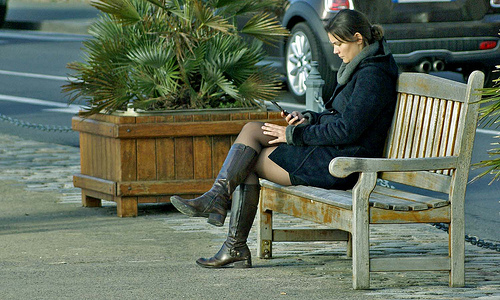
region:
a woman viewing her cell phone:
[170, 8, 399, 271]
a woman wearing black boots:
[168, 141, 262, 268]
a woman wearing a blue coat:
[268, 43, 400, 193]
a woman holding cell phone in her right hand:
[266, 98, 295, 120]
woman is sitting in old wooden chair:
[256, 69, 488, 291]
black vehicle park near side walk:
[136, 0, 498, 106]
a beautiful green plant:
[59, 1, 293, 109]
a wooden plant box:
[69, 103, 298, 218]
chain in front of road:
[0, 110, 498, 251]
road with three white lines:
[0, 31, 498, 242]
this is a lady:
[263, 26, 392, 153]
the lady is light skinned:
[257, 124, 274, 145]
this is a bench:
[354, 152, 475, 279]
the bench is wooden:
[348, 148, 396, 265]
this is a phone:
[271, 97, 301, 118]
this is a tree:
[145, 32, 218, 94]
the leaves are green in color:
[195, 49, 242, 85]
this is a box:
[91, 117, 174, 179]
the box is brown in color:
[116, 122, 177, 177]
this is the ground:
[44, 214, 134, 296]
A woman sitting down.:
[167, 6, 397, 270]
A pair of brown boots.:
[169, 139, 259, 267]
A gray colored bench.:
[259, 69, 483, 289]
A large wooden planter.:
[71, 105, 291, 217]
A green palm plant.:
[56, 0, 292, 120]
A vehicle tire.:
[284, 19, 326, 98]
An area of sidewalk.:
[0, 130, 499, 299]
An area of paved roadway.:
[0, 25, 113, 145]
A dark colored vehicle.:
[253, 0, 498, 100]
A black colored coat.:
[267, 55, 399, 190]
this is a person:
[180, 7, 422, 277]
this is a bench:
[243, 68, 492, 296]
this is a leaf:
[114, 25, 180, 92]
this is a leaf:
[183, 52, 236, 122]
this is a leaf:
[236, 62, 290, 115]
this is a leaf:
[67, 58, 147, 118]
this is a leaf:
[65, 40, 122, 102]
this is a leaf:
[99, 2, 175, 55]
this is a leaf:
[240, 2, 304, 57]